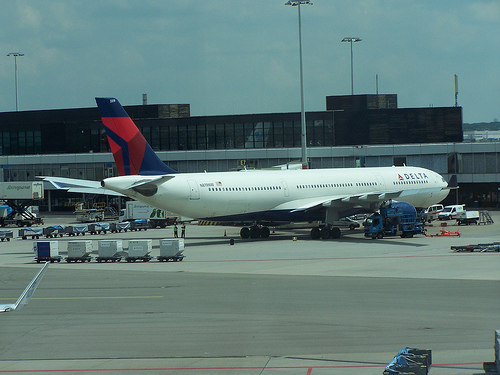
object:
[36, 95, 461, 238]
plane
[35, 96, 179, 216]
tail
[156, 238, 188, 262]
cart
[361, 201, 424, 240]
truck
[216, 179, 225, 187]
flag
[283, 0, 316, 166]
pole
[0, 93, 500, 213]
airport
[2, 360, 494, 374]
stripe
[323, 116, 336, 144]
window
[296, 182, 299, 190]
small window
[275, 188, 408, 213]
wing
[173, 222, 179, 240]
person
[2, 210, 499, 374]
tarmac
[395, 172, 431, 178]
logo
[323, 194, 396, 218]
engine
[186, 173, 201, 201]
door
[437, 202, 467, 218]
van